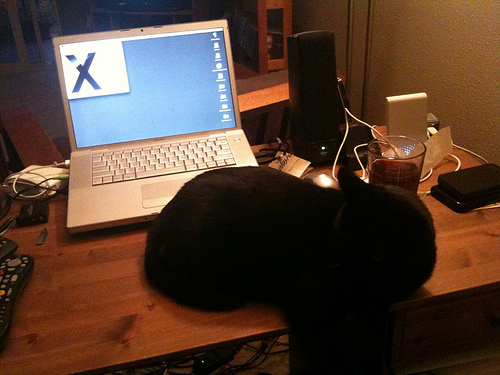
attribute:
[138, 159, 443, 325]
cat — black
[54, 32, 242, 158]
computer — laptop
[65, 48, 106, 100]
x — huge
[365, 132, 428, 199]
glass — clear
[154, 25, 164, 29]
speaker — black, white, small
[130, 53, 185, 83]
screen — bright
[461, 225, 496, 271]
table — wooden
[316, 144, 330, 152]
light — green